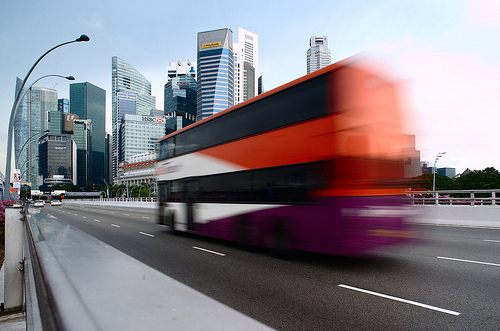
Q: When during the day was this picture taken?
A: Daytime.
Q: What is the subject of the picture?
A: Bus.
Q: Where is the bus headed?
A: Left.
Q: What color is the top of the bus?
A: Red.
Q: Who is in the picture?
A: No one.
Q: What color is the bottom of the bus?
A: Purple.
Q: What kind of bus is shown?
A: Double decker bus.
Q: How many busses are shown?
A: One.